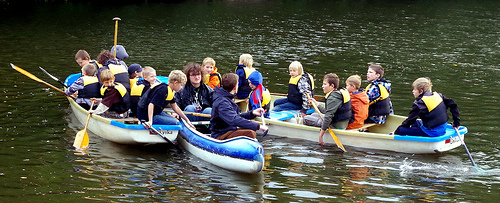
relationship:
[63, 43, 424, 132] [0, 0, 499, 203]
kids in river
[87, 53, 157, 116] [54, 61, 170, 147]
children in canoe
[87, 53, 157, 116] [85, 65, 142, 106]
children in life jackets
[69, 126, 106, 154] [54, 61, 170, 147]
oar for canoe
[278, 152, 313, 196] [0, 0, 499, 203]
ripples in river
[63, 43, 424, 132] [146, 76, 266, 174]
kids holding onto boat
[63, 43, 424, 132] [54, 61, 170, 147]
kids steering canoe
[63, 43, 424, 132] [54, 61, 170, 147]
kids rowing canoe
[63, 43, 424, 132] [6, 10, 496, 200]
kids on river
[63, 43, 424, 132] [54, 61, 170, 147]
kids in canoe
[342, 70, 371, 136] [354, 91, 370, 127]
child in life vest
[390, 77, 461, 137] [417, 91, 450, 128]
boy in life preserver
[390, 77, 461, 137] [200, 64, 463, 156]
boy on boat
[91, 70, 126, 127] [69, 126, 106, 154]
child with oar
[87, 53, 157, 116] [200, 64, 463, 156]
children in boat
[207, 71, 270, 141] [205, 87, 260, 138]
man in coat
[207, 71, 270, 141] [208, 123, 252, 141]
man in pants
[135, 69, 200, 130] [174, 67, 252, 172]
children leaning into boat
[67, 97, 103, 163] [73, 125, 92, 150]
paddle with tip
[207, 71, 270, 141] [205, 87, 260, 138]
man wearing coat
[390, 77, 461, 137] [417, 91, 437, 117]
boy wearing life preserver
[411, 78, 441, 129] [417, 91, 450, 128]
boy in life preserver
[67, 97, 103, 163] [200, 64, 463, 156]
paddle paddles boat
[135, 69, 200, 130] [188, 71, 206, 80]
children with glasses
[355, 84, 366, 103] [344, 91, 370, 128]
hood on life vest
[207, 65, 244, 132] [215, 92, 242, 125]
man wearing coat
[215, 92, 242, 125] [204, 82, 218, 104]
coat with hood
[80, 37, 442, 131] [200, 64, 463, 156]
people fill boat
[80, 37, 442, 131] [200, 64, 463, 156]
people in boat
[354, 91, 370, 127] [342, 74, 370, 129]
life vest on child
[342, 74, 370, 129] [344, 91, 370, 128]
child in life vest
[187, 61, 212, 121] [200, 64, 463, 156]
girl in boat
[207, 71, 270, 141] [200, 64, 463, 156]
man in boat